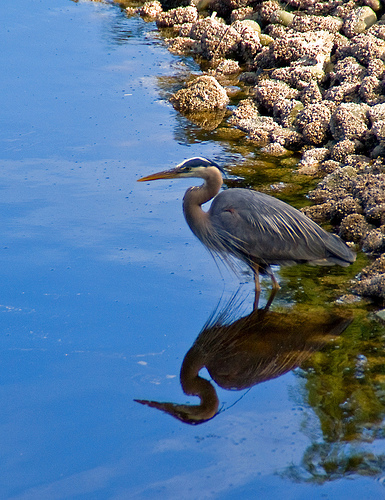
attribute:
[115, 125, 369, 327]
crane — looking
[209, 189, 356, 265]
body — grey, blue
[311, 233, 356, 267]
tail — dark grey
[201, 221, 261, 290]
feathers — thin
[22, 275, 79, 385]
water — blue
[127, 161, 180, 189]
beak — orange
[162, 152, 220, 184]
head — blue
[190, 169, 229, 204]
neck — pink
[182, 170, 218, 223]
neck — curved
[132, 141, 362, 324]
bird — blue , white 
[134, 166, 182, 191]
beak — long, orange 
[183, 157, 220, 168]
black stripe — black 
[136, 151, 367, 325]
aquatic bird — large , aquatic 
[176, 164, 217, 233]
long neck — long 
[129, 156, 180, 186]
beak — orange 